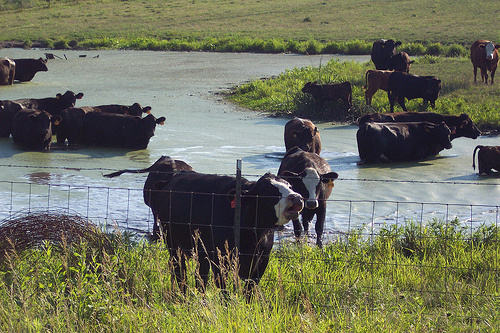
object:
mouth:
[283, 192, 307, 218]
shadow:
[240, 150, 287, 165]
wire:
[342, 185, 355, 298]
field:
[0, 1, 499, 46]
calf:
[300, 81, 359, 112]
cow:
[272, 145, 340, 248]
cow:
[99, 153, 194, 239]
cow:
[145, 170, 304, 304]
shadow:
[354, 152, 458, 172]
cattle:
[281, 115, 323, 152]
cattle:
[64, 113, 170, 150]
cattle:
[9, 107, 64, 153]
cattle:
[10, 57, 50, 83]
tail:
[101, 164, 153, 180]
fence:
[0, 159, 499, 324]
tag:
[228, 196, 237, 210]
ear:
[223, 187, 248, 203]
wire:
[7, 179, 20, 288]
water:
[0, 49, 499, 251]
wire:
[248, 194, 497, 208]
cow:
[351, 122, 454, 165]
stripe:
[299, 167, 320, 201]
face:
[298, 165, 323, 213]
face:
[266, 175, 304, 228]